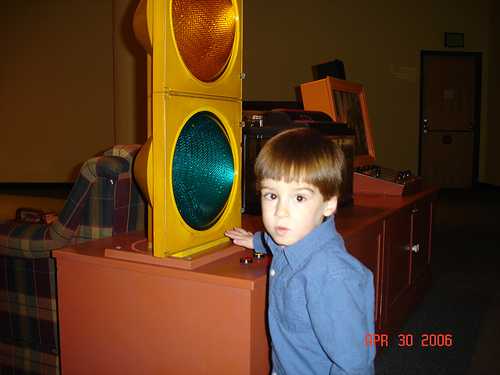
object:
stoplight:
[169, 0, 243, 82]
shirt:
[253, 216, 377, 374]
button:
[267, 267, 278, 280]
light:
[169, 105, 235, 233]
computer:
[299, 76, 426, 197]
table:
[50, 182, 450, 375]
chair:
[3, 139, 147, 375]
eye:
[293, 192, 309, 203]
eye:
[264, 191, 279, 202]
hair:
[254, 129, 344, 202]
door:
[418, 50, 476, 192]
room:
[2, 2, 499, 375]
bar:
[423, 114, 477, 134]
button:
[237, 255, 255, 266]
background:
[3, 1, 500, 374]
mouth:
[272, 223, 294, 235]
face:
[260, 167, 325, 245]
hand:
[223, 226, 256, 249]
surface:
[53, 169, 442, 281]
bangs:
[255, 146, 334, 184]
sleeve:
[303, 270, 374, 375]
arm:
[1, 207, 64, 257]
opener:
[410, 242, 422, 258]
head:
[254, 128, 344, 247]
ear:
[321, 194, 337, 216]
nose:
[273, 197, 290, 221]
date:
[364, 333, 453, 347]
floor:
[373, 228, 499, 374]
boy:
[222, 126, 377, 373]